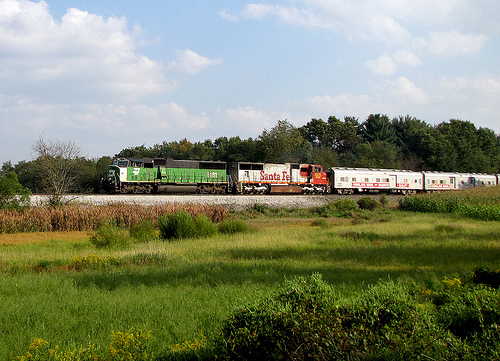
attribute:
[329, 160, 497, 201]
train cars — white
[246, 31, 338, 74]
clouds — white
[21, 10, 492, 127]
sky — blue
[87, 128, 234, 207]
train engine — green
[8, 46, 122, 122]
clouds — white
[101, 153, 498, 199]
train — green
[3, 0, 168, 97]
cloud — white 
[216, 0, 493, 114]
cloud — white 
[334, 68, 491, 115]
clouds — white, fluffy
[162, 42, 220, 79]
cloud — white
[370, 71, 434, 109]
cloud — white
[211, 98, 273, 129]
cloud — white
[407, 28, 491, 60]
cloud — white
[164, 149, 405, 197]
cars — white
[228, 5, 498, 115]
clouds — white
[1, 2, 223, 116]
clouds — white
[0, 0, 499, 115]
sky — blue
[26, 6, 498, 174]
sky — blue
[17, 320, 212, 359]
yellow flowers — tiny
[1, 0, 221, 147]
clouds — white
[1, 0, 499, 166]
sky — blue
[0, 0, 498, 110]
clouds — white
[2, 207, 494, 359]
grass — green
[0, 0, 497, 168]
clouds — white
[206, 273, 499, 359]
bush — green , short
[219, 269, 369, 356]
bush — short, green 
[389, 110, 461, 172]
tree — green, short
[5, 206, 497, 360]
field — grassy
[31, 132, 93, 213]
tree — dead 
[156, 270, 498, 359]
bush — short, green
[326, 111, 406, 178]
tree — green, short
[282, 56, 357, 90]
sky — blue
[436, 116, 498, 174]
tree — green, short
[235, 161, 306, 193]
train — white 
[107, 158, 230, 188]
engine — green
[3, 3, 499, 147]
sky — blue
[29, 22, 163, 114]
cloud — white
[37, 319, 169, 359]
flower — yellow 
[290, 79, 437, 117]
clouds — white 